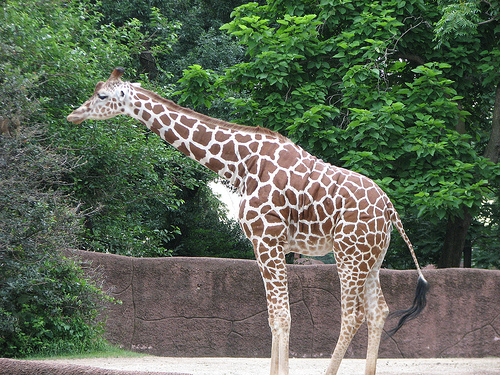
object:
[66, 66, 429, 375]
giraffe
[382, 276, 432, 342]
hair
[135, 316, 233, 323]
cracks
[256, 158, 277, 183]
spot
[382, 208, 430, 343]
tail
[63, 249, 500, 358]
concrete wall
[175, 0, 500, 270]
tree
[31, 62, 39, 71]
foilage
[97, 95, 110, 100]
eye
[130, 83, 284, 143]
mane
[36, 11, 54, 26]
leaves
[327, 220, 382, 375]
leg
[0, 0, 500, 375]
giraffe habitat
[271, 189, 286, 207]
spots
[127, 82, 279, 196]
neck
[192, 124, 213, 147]
spots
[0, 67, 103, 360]
bush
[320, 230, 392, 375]
legs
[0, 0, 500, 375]
scene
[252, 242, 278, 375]
leg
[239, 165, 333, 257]
midsection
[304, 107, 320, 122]
leaves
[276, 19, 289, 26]
leaves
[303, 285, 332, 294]
crack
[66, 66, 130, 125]
head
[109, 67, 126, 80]
horns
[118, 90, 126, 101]
ear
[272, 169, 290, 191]
spots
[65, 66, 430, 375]
body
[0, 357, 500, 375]
ground